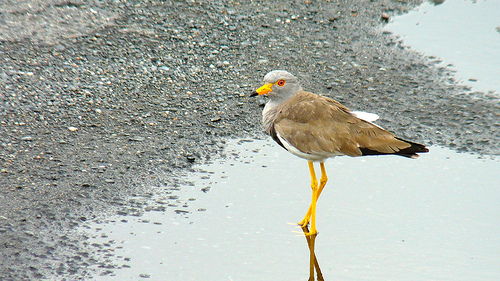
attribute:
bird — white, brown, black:
[236, 62, 427, 231]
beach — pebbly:
[9, 10, 486, 66]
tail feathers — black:
[361, 124, 435, 165]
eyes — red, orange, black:
[275, 78, 291, 91]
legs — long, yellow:
[302, 157, 325, 241]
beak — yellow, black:
[247, 80, 270, 100]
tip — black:
[246, 91, 258, 101]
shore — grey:
[419, 4, 480, 279]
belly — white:
[280, 133, 333, 162]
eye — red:
[276, 77, 290, 88]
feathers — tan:
[305, 103, 361, 147]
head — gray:
[250, 67, 305, 98]